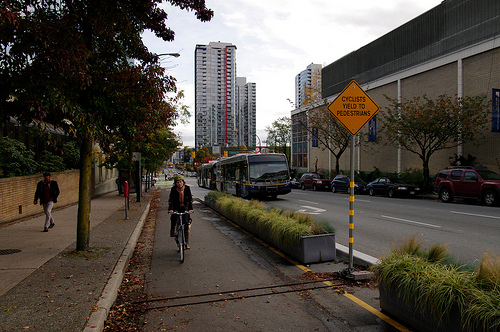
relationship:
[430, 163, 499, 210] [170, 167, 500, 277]
suv on side of road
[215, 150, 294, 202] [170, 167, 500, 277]
bus on road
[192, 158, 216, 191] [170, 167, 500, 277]
bus on road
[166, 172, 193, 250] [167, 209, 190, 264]
woman riding bicycle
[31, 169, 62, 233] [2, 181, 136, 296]
man walking on sidewalk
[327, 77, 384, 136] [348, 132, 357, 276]
sign on pole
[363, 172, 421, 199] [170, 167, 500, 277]
car on side of road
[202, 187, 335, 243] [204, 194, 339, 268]
plants in holder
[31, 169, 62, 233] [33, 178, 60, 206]
man in jacket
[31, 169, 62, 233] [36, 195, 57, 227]
man in pants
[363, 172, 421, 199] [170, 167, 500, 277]
car parked on road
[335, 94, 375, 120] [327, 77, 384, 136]
words on sign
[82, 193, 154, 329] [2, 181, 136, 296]
curb on sidewalk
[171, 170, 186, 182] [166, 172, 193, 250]
hat on woman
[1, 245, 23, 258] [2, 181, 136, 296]
manhole on sidewalk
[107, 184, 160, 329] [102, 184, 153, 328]
leaves in gutter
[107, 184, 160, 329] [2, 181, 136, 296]
leaves on sidewalk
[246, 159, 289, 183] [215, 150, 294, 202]
windshield on bus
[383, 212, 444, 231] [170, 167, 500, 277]
line in road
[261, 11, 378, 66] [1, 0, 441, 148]
clouds in sky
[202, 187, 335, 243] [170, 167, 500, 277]
plants near road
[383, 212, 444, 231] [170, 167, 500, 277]
line on road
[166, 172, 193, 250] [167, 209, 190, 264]
woman on bicycle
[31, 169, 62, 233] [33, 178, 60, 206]
man has jacket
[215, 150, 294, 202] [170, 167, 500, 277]
bus coming up road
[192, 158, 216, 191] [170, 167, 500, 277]
bus coming up road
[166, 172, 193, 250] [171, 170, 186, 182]
woman wearing hat